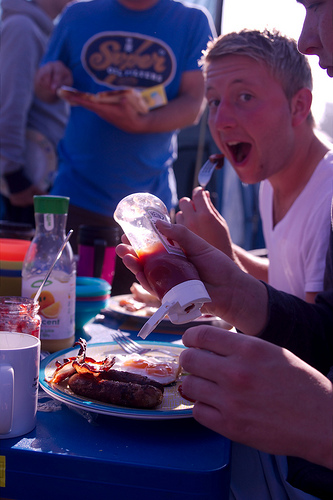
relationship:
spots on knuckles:
[222, 372, 244, 430] [217, 331, 258, 442]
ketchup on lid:
[183, 302, 194, 312] [126, 276, 217, 344]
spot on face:
[254, 161, 267, 172] [211, 36, 307, 183]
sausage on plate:
[71, 374, 161, 411] [42, 311, 245, 436]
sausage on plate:
[71, 374, 161, 411] [38, 338, 240, 421]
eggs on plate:
[102, 336, 195, 377] [104, 281, 241, 334]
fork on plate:
[111, 330, 180, 358] [37, 333, 199, 420]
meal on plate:
[70, 326, 194, 411] [153, 401, 181, 420]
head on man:
[203, 27, 312, 180] [172, 18, 333, 298]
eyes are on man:
[187, 83, 273, 114] [172, 18, 333, 298]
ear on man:
[287, 85, 313, 128] [172, 18, 333, 298]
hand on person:
[170, 323, 331, 469] [118, 1, 330, 500]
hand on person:
[113, 215, 230, 317] [118, 1, 330, 500]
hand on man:
[170, 183, 236, 265] [172, 18, 333, 298]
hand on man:
[32, 57, 76, 106] [31, 1, 219, 254]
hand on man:
[73, 91, 144, 138] [31, 1, 219, 254]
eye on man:
[205, 98, 222, 107] [172, 18, 333, 298]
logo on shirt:
[76, 26, 183, 103] [47, 6, 197, 208]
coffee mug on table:
[0, 321, 61, 443] [0, 219, 253, 489]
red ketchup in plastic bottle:
[137, 240, 206, 298] [110, 188, 211, 341]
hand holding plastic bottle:
[122, 232, 232, 302] [110, 188, 211, 341]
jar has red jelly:
[0, 291, 41, 337] [0, 298, 44, 341]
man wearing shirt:
[187, 18, 319, 222] [120, 6, 328, 343]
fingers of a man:
[178, 324, 249, 438] [172, 18, 333, 298]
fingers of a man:
[116, 234, 156, 300] [172, 18, 333, 298]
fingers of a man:
[172, 186, 210, 228] [172, 18, 333, 298]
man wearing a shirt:
[172, 18, 333, 298] [250, 148, 331, 296]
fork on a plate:
[197, 157, 215, 188] [37, 333, 199, 420]